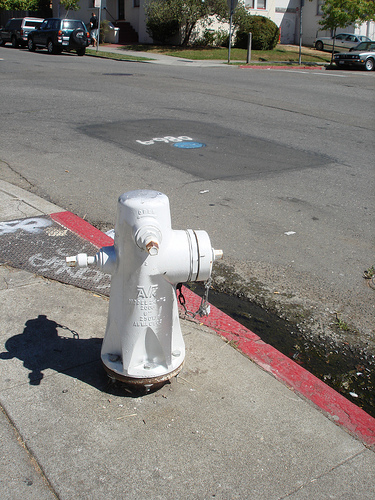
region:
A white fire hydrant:
[70, 163, 231, 391]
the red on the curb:
[253, 348, 374, 435]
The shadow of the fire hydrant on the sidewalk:
[6, 312, 96, 403]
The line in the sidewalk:
[0, 384, 64, 489]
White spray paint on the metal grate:
[0, 213, 64, 283]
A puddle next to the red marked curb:
[238, 298, 370, 382]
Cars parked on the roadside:
[0, 13, 90, 59]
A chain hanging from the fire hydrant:
[176, 283, 211, 324]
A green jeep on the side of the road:
[25, 17, 89, 56]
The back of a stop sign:
[223, 1, 238, 62]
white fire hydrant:
[65, 188, 224, 394]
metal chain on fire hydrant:
[176, 278, 213, 318]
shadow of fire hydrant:
[0, 313, 172, 398]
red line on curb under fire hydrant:
[48, 209, 373, 452]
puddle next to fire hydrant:
[187, 284, 373, 420]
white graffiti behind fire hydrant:
[0, 217, 110, 288]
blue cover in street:
[173, 141, 201, 149]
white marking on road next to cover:
[135, 136, 190, 145]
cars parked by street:
[0, 16, 374, 71]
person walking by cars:
[88, 11, 98, 46]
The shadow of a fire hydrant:
[0, 301, 183, 430]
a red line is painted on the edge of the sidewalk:
[40, 192, 372, 455]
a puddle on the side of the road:
[148, 223, 374, 414]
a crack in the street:
[0, 155, 47, 189]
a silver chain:
[173, 279, 223, 332]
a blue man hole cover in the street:
[169, 136, 207, 156]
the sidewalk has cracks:
[2, 183, 366, 496]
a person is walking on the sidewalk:
[82, 8, 110, 62]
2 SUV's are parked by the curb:
[1, 8, 92, 59]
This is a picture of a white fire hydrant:
[66, 164, 240, 401]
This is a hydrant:
[62, 204, 211, 472]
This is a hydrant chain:
[173, 276, 213, 311]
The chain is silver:
[177, 286, 238, 332]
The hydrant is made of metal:
[109, 123, 216, 313]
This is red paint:
[228, 306, 350, 452]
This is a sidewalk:
[19, 395, 114, 467]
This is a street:
[138, 166, 353, 322]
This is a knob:
[57, 249, 107, 280]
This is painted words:
[32, 227, 89, 320]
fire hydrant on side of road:
[62, 189, 222, 394]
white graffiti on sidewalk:
[0, 215, 113, 289]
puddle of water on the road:
[186, 272, 374, 413]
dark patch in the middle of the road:
[75, 118, 340, 178]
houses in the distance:
[50, 0, 373, 41]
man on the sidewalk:
[90, 15, 101, 49]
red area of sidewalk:
[49, 213, 372, 446]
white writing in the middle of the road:
[135, 133, 193, 146]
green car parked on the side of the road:
[27, 18, 87, 57]